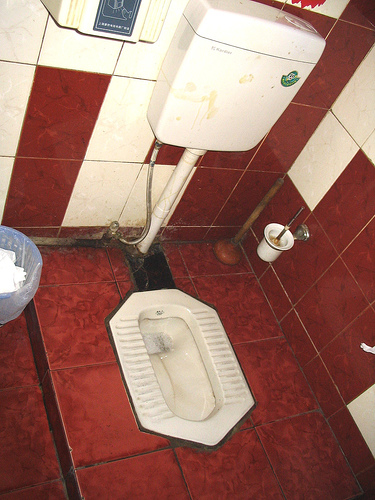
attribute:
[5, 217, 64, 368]
bin — blue 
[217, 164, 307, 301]
plunger — old , dirty 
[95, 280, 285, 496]
urinal — white 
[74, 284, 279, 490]
urinal — white 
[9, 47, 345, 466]
bathroom — old , dirty 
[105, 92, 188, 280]
line — dirty 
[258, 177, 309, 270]
brush — dirty 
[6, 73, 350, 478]
bathroom — white , red 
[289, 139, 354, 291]
tile — red , white 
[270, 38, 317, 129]
sticker — Green 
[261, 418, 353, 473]
floor — red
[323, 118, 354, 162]
tile — white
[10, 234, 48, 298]
trashcan — blue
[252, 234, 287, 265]
cleaner container — white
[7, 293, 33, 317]
trash bag — clear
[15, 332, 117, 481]
tile — red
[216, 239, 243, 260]
plunger — red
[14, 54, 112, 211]
tiles — red, white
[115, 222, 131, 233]
dust bunnies — many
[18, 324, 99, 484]
step down — right here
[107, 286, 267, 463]
toilet — recessed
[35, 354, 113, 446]
tile — red, square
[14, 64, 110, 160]
tile — red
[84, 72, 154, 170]
tile — white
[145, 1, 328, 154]
toilet tank — white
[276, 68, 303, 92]
sticker — green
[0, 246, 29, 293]
paper — white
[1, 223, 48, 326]
basket — white